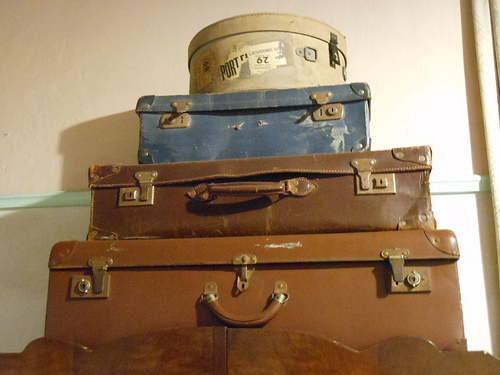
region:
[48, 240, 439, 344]
this is a box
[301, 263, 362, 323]
the box is brown in color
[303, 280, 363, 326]
the box is metallic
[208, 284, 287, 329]
this is the handle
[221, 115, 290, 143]
the box is blue in color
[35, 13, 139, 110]
this is the wall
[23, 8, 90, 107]
the wall is whit in color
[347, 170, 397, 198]
this is the lock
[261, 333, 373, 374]
this is a cupboard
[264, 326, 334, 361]
the cupboard is brown in color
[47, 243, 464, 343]
tan suitcase in stack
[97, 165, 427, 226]
brown suitcase in stack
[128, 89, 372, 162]
blue suitcase in stack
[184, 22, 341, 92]
round white suitcase in stack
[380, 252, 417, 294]
metal latch on suitcase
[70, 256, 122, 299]
metal latch on suitcase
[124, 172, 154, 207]
metal latch on suitcase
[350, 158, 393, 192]
metal latch on suitcase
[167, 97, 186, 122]
metal latch on suitcase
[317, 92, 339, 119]
metal latch on suitcase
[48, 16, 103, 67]
this is the wall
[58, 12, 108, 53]
the wall is white in color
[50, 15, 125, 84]
the wall is clean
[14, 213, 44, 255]
the wall is made of stone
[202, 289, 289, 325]
this is a handle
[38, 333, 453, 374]
the bed is wooden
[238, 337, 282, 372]
the wood is brown in color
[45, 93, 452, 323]
these are some suitcases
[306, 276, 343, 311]
the suitcase is brown in color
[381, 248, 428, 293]
this is a lock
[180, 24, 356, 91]
A round metalic box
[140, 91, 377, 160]
A blue metalic box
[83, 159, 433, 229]
A brown metalic box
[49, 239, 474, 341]
A brown metalic box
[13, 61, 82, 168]
A white house wall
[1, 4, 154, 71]
A white house wall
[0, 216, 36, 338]
A white house wall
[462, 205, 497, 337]
A white house wall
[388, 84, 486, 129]
A white house wall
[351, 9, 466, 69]
A white house wall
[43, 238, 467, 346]
brown leather suitcase on floor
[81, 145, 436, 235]
dark brown leather suitcase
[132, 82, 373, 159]
worn blue leather suitcase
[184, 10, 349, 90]
white leather hat box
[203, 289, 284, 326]
brown handle on suitcase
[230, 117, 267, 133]
holes in blue suitcase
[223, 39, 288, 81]
white sticker on hat box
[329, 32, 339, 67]
metal latch on hat box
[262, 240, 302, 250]
scratch on leather suitcase